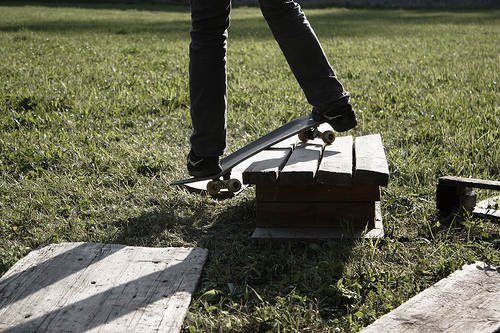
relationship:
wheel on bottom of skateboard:
[298, 128, 308, 141] [163, 84, 357, 206]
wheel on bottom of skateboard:
[226, 178, 240, 193] [163, 84, 357, 206]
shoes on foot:
[316, 100, 360, 133] [303, 89, 358, 131]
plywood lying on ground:
[1, 240, 211, 331] [37, 57, 417, 318]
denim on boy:
[192, 3, 342, 150] [186, 0, 359, 178]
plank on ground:
[250, 104, 399, 232] [132, 127, 422, 304]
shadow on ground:
[115, 177, 252, 327] [5, 5, 158, 238]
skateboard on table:
[177, 105, 339, 196] [240, 130, 391, 240]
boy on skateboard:
[186, 0, 359, 178] [177, 105, 339, 196]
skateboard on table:
[177, 105, 339, 196] [253, 127, 393, 244]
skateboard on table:
[177, 105, 339, 196] [238, 102, 407, 244]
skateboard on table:
[177, 105, 339, 196] [246, 145, 378, 197]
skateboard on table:
[177, 105, 339, 196] [236, 125, 394, 243]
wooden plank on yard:
[0, 233, 210, 331] [10, 10, 187, 232]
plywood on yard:
[354, 260, 500, 332] [98, 45, 473, 245]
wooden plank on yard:
[0, 233, 210, 331] [98, 45, 473, 245]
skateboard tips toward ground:
[177, 105, 339, 196] [36, 184, 256, 266]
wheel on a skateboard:
[298, 128, 308, 141] [177, 105, 339, 196]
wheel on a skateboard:
[321, 131, 331, 145] [177, 105, 339, 196]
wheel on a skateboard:
[226, 178, 240, 193] [177, 105, 339, 196]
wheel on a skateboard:
[207, 178, 219, 194] [177, 105, 339, 196]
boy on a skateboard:
[186, 0, 359, 178] [139, 77, 376, 205]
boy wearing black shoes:
[186, 0, 359, 178] [186, 152, 223, 178]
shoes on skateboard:
[205, 79, 360, 157] [142, 110, 354, 204]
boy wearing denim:
[186, 0, 359, 178] [187, 3, 350, 154]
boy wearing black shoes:
[186, 0, 359, 178] [180, 96, 360, 175]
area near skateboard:
[2, 12, 482, 327] [172, 113, 353, 200]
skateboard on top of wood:
[177, 105, 339, 196] [243, 127, 395, 248]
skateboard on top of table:
[177, 105, 339, 196] [246, 134, 408, 241]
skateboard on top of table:
[177, 105, 339, 196] [240, 130, 391, 240]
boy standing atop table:
[186, 0, 359, 178] [251, 121, 401, 235]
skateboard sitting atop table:
[177, 105, 339, 196] [251, 121, 401, 235]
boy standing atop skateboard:
[186, 0, 359, 178] [177, 105, 339, 196]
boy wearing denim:
[188, 0, 351, 155] [187, 3, 350, 154]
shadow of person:
[0, 177, 345, 332] [164, 12, 390, 197]